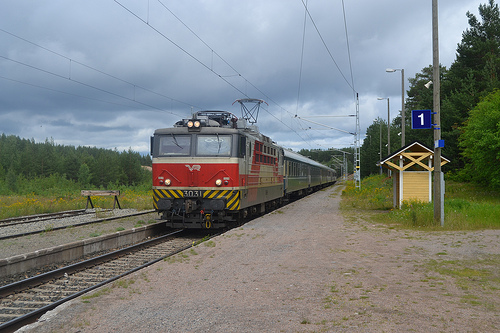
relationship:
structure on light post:
[377, 141, 448, 211] [431, 3, 445, 226]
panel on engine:
[131, 182, 245, 230] [149, 175, 238, 244]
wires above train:
[12, 10, 365, 121] [146, 106, 339, 233]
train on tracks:
[146, 106, 339, 233] [1, 227, 212, 331]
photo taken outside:
[3, 1, 497, 331] [3, 5, 498, 325]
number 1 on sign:
[410, 109, 426, 125] [402, 104, 436, 131]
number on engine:
[183, 189, 203, 197] [150, 125, 285, 230]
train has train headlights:
[114, 85, 316, 324] [178, 114, 218, 139]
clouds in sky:
[0, 0, 499, 144] [0, 0, 430, 67]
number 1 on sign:
[417, 112, 426, 125] [410, 107, 433, 124]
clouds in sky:
[5, 3, 480, 144] [1, 3, 499, 148]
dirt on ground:
[261, 267, 311, 297] [329, 231, 462, 303]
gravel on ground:
[357, 253, 418, 307] [329, 231, 462, 303]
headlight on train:
[213, 177, 230, 193] [139, 100, 337, 236]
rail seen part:
[4, 235, 193, 322] [55, 260, 82, 274]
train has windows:
[146, 106, 339, 233] [155, 133, 234, 158]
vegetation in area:
[27, 146, 114, 180] [4, 134, 156, 197]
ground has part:
[1, 176, 493, 330] [306, 245, 398, 321]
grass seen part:
[345, 170, 500, 237] [413, 198, 429, 225]